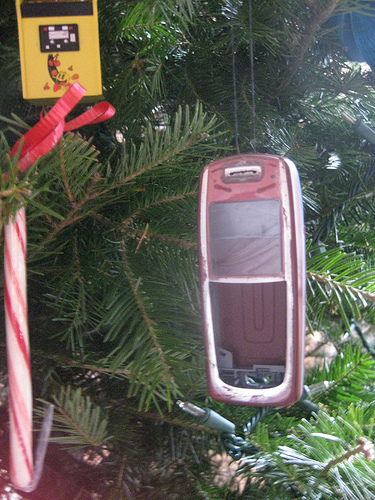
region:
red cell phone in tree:
[195, 149, 316, 415]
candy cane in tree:
[4, 167, 33, 497]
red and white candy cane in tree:
[6, 162, 45, 495]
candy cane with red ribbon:
[0, 79, 117, 494]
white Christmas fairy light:
[175, 388, 251, 439]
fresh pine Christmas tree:
[5, 3, 373, 492]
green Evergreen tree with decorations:
[4, 14, 372, 495]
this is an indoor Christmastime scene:
[1, 12, 371, 492]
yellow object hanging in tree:
[15, 1, 118, 109]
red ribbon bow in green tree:
[3, 80, 116, 180]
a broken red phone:
[176, 133, 331, 424]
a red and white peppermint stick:
[0, 180, 42, 498]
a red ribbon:
[13, 91, 115, 172]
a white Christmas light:
[145, 369, 325, 466]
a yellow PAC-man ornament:
[15, 0, 103, 108]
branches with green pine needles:
[55, 154, 188, 399]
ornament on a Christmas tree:
[6, 3, 340, 494]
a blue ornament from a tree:
[326, 0, 374, 73]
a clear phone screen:
[202, 200, 293, 277]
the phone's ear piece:
[210, 156, 284, 191]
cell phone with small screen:
[199, 147, 304, 402]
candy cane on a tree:
[3, 173, 53, 492]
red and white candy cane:
[0, 189, 33, 489]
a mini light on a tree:
[173, 398, 249, 446]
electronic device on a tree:
[12, 0, 110, 103]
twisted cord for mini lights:
[242, 409, 267, 435]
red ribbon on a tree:
[4, 84, 112, 175]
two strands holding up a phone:
[214, 0, 261, 156]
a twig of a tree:
[111, 108, 226, 185]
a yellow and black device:
[16, 0, 102, 96]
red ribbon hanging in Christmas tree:
[12, 88, 127, 181]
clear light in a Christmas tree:
[173, 378, 292, 471]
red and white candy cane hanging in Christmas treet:
[7, 181, 46, 498]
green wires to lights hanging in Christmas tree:
[229, 402, 294, 477]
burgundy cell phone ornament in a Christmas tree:
[191, 151, 315, 425]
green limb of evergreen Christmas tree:
[53, 379, 124, 469]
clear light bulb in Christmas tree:
[331, 97, 373, 174]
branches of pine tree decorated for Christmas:
[67, 158, 196, 317]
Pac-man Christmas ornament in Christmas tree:
[6, 1, 130, 107]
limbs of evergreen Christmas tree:
[284, 4, 366, 109]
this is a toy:
[202, 171, 300, 405]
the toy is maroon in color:
[204, 168, 308, 406]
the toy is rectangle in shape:
[199, 161, 313, 405]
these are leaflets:
[113, 332, 181, 398]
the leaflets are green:
[117, 321, 183, 395]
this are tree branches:
[55, 348, 180, 494]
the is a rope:
[196, 405, 290, 478]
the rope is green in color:
[212, 413, 300, 478]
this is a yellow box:
[13, 7, 109, 100]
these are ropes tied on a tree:
[226, 9, 276, 155]